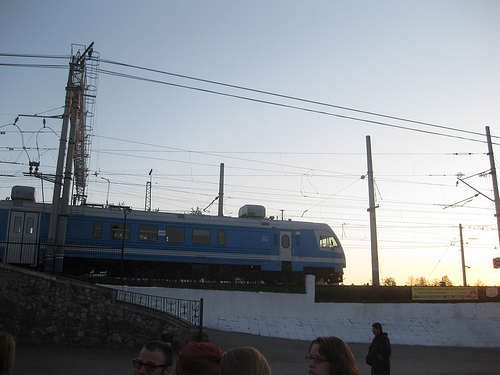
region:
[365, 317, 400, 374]
man in black clothing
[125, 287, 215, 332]
black metal fencing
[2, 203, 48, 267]
grey door on side of train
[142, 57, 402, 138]
power lines running beside train tracks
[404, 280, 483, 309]
large yellow sign on fencing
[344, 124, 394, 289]
large wooden electric pole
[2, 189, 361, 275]
blue and white train engine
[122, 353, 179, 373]
man in black sunglasses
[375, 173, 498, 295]
setting evening sun in sky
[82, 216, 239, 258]
row of windows on side of train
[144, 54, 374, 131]
power lines running along track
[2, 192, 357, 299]
blue and white train on tracks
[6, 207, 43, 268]
white door on side of train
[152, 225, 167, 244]
white sign on side of train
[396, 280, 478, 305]
yellow sign on wall beside tracks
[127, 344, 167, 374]
man in black glasses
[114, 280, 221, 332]
black metal guard railing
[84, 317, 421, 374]
group of people standing beside train tracks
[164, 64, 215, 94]
electrical wires in the air.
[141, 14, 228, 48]
blue sky above wires.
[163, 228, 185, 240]
window on the train.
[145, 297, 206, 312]
railing along the walkway.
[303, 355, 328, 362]
glasses on woman's face.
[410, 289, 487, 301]
sign on the concrete.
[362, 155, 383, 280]
pole supporting the wires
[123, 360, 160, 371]
glasses on man's face.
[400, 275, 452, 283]
trees in the distance.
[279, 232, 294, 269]
door on side of train.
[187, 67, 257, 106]
wires in the air.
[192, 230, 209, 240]
window on the train.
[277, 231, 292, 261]
door on the train.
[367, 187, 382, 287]
pole supporting the wires.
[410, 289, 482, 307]
sign on the wall.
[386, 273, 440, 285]
trees in the distance.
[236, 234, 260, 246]
blue paint on train.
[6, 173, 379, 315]
train on a track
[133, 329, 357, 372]
heads of people by a train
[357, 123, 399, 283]
utility pole on the ground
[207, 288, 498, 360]
white wall by train tracks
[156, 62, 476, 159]
electrical wires above train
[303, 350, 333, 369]
glasses on a woman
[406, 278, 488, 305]
sign on a wall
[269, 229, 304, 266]
door to a train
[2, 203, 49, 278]
back doors of a train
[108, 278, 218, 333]
fence by a train stop